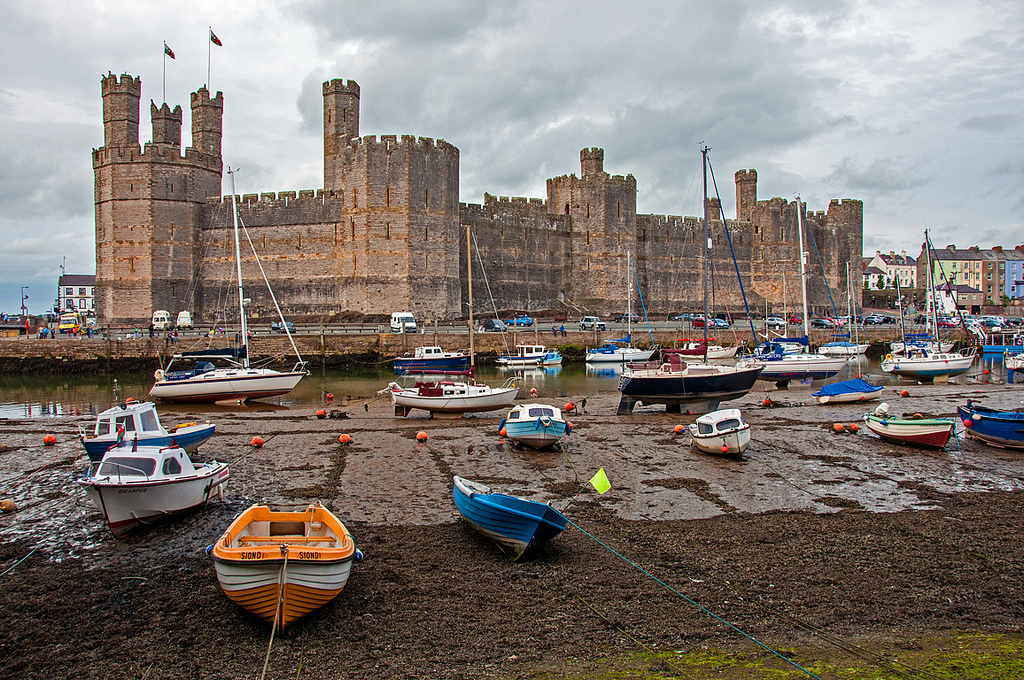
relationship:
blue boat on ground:
[454, 475, 567, 561] [5, 386, 1021, 669]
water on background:
[0, 332, 1021, 427] [2, 212, 1018, 381]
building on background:
[96, 70, 863, 323] [10, 85, 1020, 353]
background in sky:
[0, 0, 1024, 326] [2, 8, 1018, 214]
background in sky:
[0, 0, 1024, 326] [1, 273, 49, 300]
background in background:
[0, 0, 1024, 326] [0, 0, 1024, 326]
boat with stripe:
[686, 408, 753, 456] [690, 422, 745, 438]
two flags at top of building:
[144, 20, 244, 55] [89, 67, 869, 338]